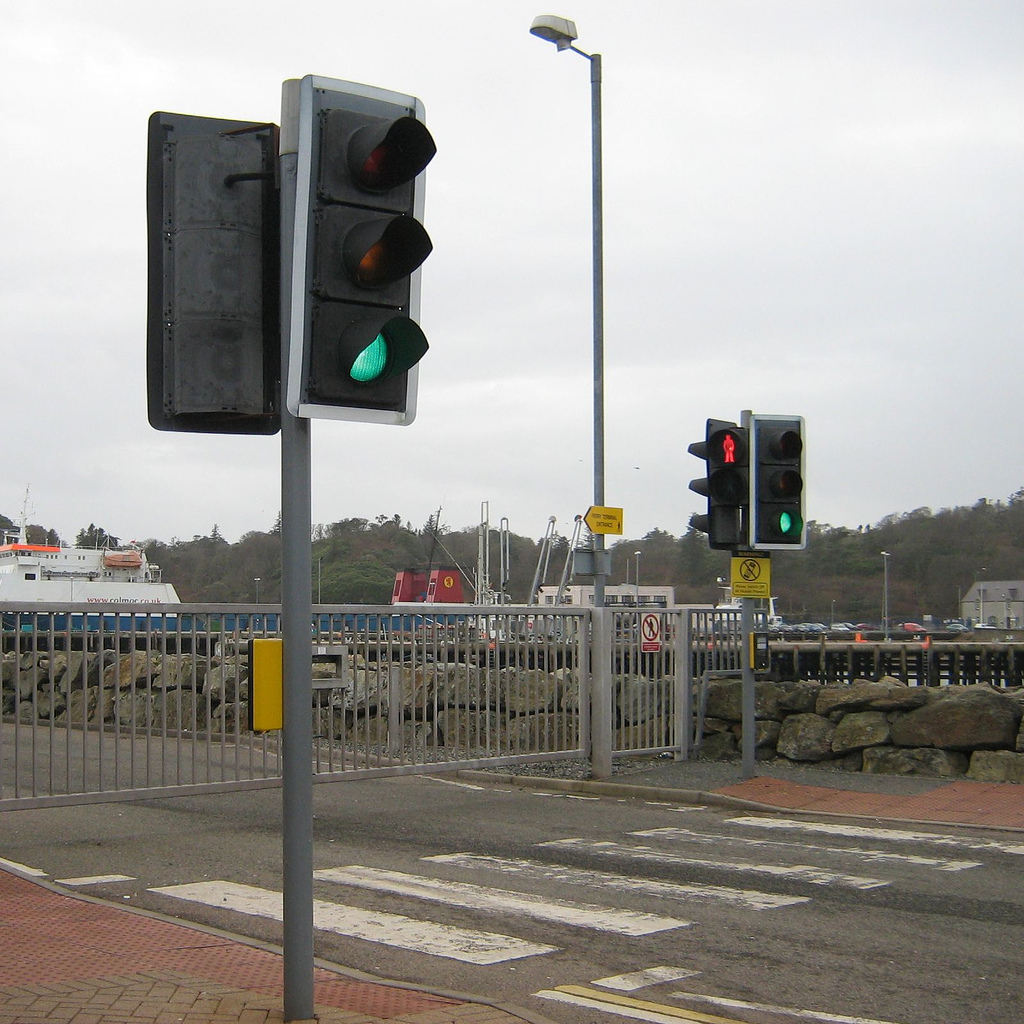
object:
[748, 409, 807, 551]
signal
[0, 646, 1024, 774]
wall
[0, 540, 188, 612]
ship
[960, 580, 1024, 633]
building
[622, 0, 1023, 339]
cloud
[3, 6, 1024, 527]
sky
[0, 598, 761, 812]
rails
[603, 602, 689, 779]
gate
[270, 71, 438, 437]
traffic lights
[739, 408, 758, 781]
pole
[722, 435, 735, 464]
light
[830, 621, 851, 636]
cars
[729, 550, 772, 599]
sign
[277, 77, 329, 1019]
pole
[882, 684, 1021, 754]
rocks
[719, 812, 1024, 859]
line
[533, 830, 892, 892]
line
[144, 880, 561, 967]
line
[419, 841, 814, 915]
line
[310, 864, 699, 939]
line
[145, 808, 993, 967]
pavement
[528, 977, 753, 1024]
line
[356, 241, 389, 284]
light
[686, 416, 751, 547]
traffic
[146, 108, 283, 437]
bank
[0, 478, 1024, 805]
background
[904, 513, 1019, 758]
distance